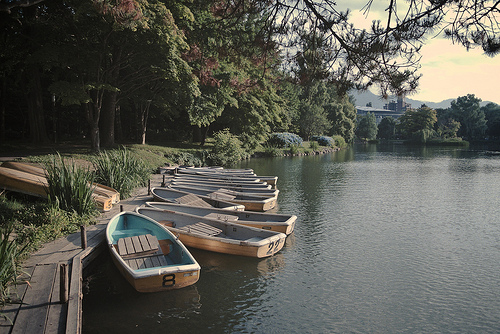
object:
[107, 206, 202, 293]
boat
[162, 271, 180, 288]
part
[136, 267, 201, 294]
back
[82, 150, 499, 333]
water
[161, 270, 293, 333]
ripples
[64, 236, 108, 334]
edge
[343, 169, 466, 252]
part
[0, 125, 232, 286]
terrain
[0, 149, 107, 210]
part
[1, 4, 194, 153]
tree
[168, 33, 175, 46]
leaves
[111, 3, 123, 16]
leaves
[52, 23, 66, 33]
leaves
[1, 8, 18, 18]
leaves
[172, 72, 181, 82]
leaves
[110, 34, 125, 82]
branch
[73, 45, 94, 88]
branch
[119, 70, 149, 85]
branch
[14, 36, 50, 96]
branch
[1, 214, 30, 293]
plantations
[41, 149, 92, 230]
plantations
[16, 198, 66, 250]
plantations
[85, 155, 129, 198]
plantations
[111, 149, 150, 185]
plantations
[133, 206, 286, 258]
boat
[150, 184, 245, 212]
boat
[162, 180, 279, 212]
boat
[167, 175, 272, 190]
boat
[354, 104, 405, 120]
house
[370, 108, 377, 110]
section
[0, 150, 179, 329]
dock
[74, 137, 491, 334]
river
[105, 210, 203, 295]
row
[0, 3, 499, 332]
day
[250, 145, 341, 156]
bridge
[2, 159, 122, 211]
walkway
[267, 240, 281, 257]
number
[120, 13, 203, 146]
tree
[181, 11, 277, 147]
tree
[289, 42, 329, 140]
tree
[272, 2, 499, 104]
sky